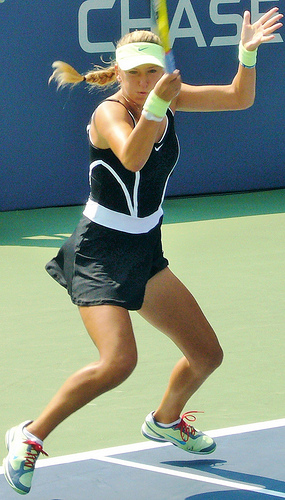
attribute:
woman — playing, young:
[4, 3, 283, 495]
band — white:
[82, 196, 165, 237]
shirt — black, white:
[84, 98, 182, 233]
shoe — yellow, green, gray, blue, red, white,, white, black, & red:
[3, 419, 40, 494]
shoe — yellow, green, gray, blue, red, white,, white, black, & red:
[141, 409, 218, 458]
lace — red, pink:
[23, 439, 49, 470]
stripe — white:
[0, 415, 285, 475]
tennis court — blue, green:
[0, 188, 282, 496]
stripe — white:
[95, 455, 281, 498]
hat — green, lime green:
[112, 40, 167, 70]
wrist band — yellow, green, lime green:
[235, 42, 256, 66]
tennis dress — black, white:
[45, 93, 182, 311]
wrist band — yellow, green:
[142, 90, 173, 118]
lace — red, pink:
[177, 408, 200, 445]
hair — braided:
[47, 27, 163, 91]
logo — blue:
[162, 434, 186, 448]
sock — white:
[155, 418, 186, 426]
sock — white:
[23, 430, 46, 446]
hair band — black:
[82, 74, 89, 84]